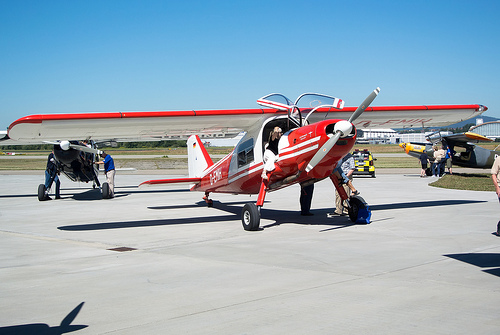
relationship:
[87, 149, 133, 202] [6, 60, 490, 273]
man next to airplane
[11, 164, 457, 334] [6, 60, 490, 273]
area for airplanes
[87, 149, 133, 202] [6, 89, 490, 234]
man looking in airplane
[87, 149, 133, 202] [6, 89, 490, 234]
man looking at airplane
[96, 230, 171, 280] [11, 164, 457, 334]
grate in area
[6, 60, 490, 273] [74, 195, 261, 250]
airplane has shadow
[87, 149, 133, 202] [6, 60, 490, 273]
man touching airplane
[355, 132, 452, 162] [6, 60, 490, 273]
building behind airplane